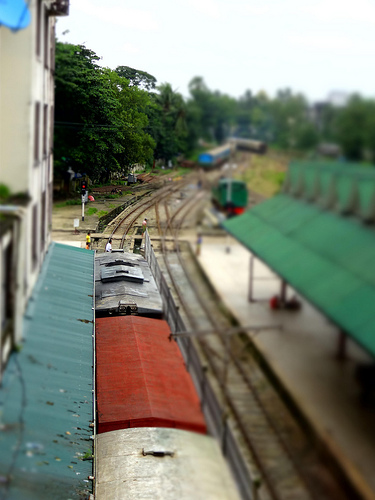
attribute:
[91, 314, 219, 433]
train — red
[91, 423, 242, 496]
train — tan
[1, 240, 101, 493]
roof — green, teal 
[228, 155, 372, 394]
pavilion — small 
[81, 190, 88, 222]
pole — small 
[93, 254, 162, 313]
roof — brown 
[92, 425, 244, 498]
roof — tan 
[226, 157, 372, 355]
roof — green 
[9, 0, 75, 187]
building — large, white